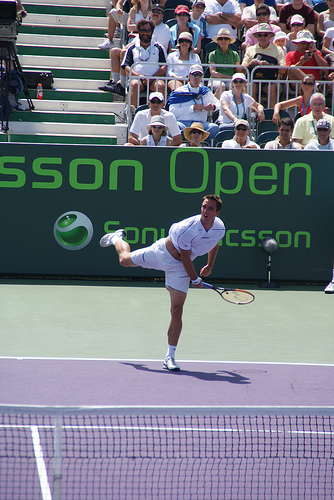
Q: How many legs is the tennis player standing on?
A: One.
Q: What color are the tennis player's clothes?
A: White.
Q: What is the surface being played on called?
A: Tennis court.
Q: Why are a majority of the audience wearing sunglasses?
A: It is sunny.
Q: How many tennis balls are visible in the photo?
A: One.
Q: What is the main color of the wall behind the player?
A: Green.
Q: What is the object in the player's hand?
A: Tennis racket.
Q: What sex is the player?
A: Male.